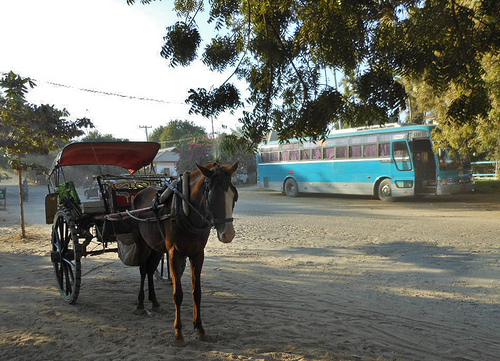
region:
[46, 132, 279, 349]
the buggie is attatched to the horse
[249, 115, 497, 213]
the bus is blue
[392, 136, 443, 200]
the door is open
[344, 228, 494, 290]
the shadow is on the ground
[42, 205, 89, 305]
the wheel is big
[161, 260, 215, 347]
the horse has front legs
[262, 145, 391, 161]
the bus has windows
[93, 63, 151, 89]
the sky is gray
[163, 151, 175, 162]
the roof is black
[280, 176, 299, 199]
the bus has a wheel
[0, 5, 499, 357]
photo of a rural area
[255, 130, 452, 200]
A large teal colored bus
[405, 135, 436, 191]
boarding door is open on bus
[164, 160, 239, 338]
A dark brown horse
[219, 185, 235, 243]
horse has white strip of fur on face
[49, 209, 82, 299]
The wheel of a buggy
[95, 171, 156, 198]
driver seat of the buggy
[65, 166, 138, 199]
the riders area for buggy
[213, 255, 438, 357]
ground has a lot of sand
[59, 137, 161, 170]
a sun shade for the buggy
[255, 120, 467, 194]
blue and silver passenger bus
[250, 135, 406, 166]
row of passenger windows on bus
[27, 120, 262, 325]
horse and buggy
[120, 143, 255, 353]
brown and white horse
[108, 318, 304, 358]
horse foot prints in the sand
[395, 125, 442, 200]
bus door open to let people on and off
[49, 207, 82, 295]
large black wheel of carriage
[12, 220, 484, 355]
shadow of tree on the ground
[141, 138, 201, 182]
white building in the background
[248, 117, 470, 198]
bus parked on side of road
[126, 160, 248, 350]
a horse used to pull a cart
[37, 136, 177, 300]
cart or buggy to be pulled by a horse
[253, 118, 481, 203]
a blue and white bus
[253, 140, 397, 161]
side windows of a bus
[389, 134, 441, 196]
an open door on a bus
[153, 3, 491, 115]
tree branches over hanging the road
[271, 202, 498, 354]
dirt road with tire tracks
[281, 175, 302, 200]
the back wheel of a bus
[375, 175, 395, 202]
the front wheel of a bus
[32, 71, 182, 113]
birds sitting on a wire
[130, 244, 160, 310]
two legs on the horse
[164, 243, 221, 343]
two legs on the horse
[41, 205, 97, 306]
wheel on the carriage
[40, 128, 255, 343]
horse is pulling a carriage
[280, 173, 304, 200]
tire on the bus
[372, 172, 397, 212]
tire on the bus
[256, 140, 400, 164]
windows on the bus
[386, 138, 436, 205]
door on the bus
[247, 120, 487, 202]
the bus is blue and silver